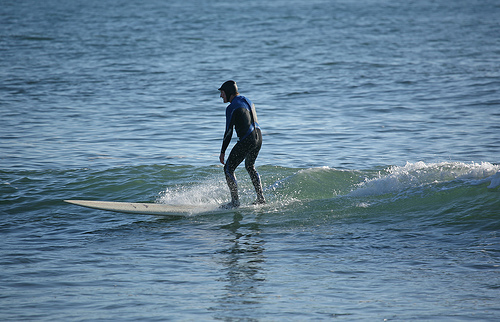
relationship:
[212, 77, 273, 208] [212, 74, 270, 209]
wet suit on man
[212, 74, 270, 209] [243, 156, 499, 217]
man riding wave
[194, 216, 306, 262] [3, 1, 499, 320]
light on water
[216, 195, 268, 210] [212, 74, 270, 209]
feet of man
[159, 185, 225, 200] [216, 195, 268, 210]
spray around feet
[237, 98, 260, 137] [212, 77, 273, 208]
stripes on wet suit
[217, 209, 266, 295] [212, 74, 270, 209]
reflection of man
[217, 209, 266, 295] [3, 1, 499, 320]
reflection in water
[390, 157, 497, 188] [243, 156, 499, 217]
top of wave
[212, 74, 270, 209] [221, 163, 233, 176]
man has knee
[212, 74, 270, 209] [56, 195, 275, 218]
man on surfboard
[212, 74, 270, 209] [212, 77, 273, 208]
man wearing wet suit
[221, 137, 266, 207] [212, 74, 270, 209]
legs of man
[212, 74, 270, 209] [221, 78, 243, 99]
man wearing hat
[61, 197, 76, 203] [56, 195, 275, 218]
tip of surfboard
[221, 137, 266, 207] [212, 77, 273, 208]
legs in wet suit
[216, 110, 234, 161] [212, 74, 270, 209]
arm of man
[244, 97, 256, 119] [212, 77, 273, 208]
zipper of wet suit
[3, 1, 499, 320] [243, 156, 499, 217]
water from wave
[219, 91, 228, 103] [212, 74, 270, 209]
face of man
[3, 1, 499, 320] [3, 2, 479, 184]
water of ocean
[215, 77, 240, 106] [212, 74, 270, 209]
head of man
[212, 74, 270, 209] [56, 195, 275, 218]
man riding surfboard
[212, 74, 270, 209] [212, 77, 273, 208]
man in wet suit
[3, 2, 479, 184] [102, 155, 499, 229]
ocean with waves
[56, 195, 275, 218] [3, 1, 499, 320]
surfboard through water